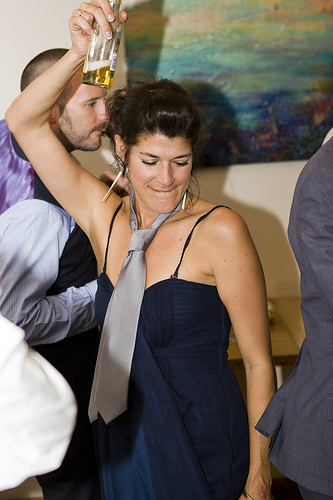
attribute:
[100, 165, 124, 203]
earring — White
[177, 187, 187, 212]
ear ring — white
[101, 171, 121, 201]
earring — White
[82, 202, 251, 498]
dress — blue, Navy 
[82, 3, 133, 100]
bottle — glass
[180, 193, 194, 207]
earring — White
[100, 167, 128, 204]
earring — White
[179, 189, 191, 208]
ear ring — White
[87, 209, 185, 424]
tie — silver